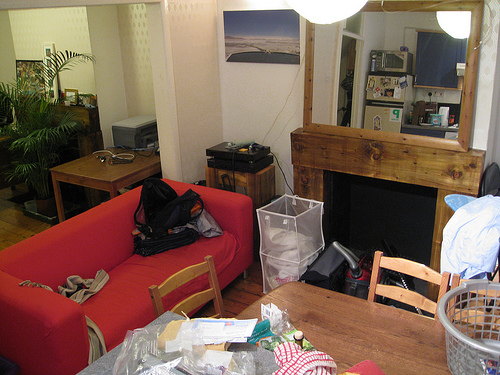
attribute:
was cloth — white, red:
[272, 339, 336, 374]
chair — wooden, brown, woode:
[368, 250, 448, 311]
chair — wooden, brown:
[150, 256, 227, 322]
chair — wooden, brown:
[448, 276, 499, 327]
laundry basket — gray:
[437, 279, 499, 374]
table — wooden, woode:
[225, 281, 494, 372]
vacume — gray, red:
[332, 236, 408, 307]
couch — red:
[1, 171, 254, 374]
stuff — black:
[130, 177, 214, 258]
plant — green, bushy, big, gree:
[0, 44, 95, 199]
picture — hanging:
[224, 9, 301, 65]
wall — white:
[3, 3, 499, 197]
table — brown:
[47, 145, 163, 223]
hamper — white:
[258, 188, 325, 296]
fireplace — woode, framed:
[290, 125, 490, 317]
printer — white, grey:
[111, 114, 156, 153]